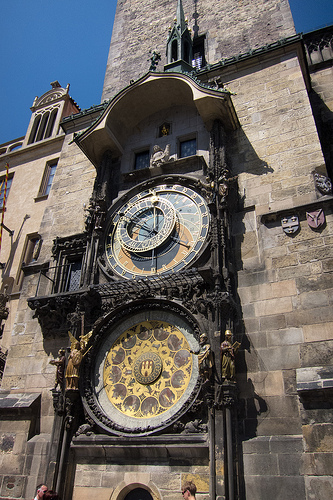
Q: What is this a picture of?
A: A clock.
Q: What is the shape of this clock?
A: Round.